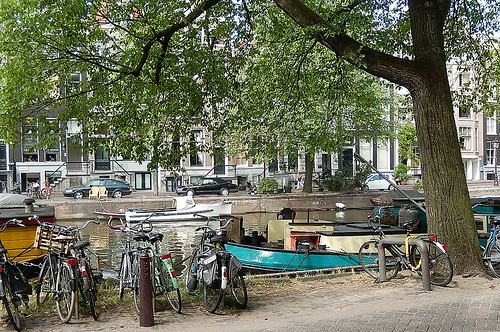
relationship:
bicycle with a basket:
[30, 211, 73, 305] [40, 223, 69, 253]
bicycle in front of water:
[357, 205, 454, 287] [237, 198, 300, 214]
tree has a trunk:
[400, 68, 471, 224] [409, 68, 464, 156]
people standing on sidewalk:
[27, 177, 59, 200] [146, 191, 178, 203]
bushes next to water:
[322, 168, 365, 194] [237, 198, 300, 214]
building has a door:
[188, 128, 322, 170] [214, 146, 230, 176]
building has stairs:
[188, 128, 322, 170] [43, 172, 70, 191]